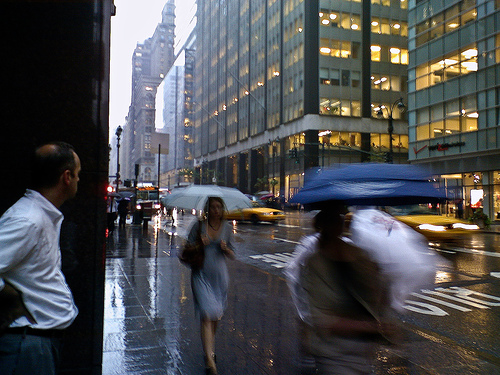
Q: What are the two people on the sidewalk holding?
A: Umbrella.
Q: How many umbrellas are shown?
A: Two.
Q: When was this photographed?
A: Daytime.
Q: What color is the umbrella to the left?
A: White.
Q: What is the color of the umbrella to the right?
A: Blue.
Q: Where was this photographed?
A: City.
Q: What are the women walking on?
A: The sidewalk.